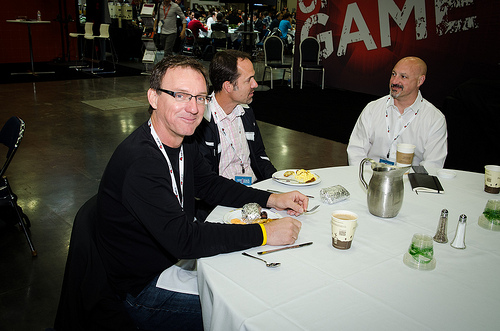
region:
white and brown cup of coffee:
[326, 206, 361, 253]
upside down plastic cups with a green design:
[402, 226, 440, 278]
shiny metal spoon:
[238, 246, 285, 275]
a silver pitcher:
[355, 155, 415, 220]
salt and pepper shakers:
[432, 203, 470, 252]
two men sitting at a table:
[70, 51, 309, 326]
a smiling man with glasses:
[77, 51, 208, 324]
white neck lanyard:
[145, 140, 187, 211]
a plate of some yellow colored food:
[267, 162, 324, 190]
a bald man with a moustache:
[342, 46, 459, 170]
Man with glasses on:
[160, 85, 221, 113]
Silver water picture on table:
[354, 150, 409, 220]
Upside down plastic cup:
[393, 232, 450, 267]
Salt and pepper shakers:
[432, 197, 474, 248]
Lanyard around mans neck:
[380, 98, 429, 147]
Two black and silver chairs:
[264, 35, 334, 94]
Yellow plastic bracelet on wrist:
[244, 218, 279, 248]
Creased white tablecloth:
[269, 270, 441, 329]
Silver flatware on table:
[243, 241, 323, 271]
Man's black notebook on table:
[410, 169, 450, 192]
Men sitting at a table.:
[83, 38, 309, 327]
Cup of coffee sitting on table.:
[326, 208, 363, 255]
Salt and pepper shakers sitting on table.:
[430, 204, 478, 250]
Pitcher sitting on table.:
[356, 156, 417, 221]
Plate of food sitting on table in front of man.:
[270, 163, 322, 190]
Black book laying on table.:
[404, 165, 451, 203]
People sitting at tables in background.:
[173, 4, 298, 61]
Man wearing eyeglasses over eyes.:
[151, 82, 215, 107]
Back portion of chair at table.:
[2, 112, 52, 262]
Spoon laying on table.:
[241, 246, 287, 274]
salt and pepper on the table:
[435, 203, 480, 262]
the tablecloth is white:
[244, 277, 311, 313]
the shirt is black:
[82, 118, 191, 238]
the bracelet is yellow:
[249, 215, 273, 250]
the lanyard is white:
[151, 139, 195, 194]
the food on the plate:
[265, 157, 326, 200]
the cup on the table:
[317, 202, 357, 261]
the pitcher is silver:
[352, 134, 407, 219]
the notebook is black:
[404, 167, 438, 201]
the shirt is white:
[342, 94, 454, 181]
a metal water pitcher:
[356, 145, 419, 224]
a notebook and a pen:
[395, 166, 450, 198]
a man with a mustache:
[366, 47, 438, 105]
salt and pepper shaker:
[430, 206, 471, 246]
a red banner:
[296, 3, 496, 75]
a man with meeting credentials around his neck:
[55, 53, 305, 323]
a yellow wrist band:
[240, 210, 271, 268]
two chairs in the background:
[247, 26, 334, 101]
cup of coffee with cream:
[320, 205, 363, 256]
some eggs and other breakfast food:
[270, 159, 326, 188]